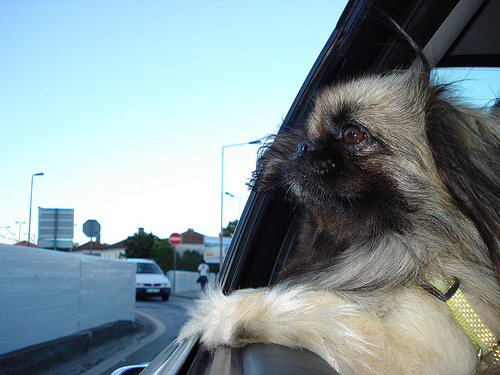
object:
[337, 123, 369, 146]
eye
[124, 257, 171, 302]
van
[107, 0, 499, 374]
car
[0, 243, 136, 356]
wall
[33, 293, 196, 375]
road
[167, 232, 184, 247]
sign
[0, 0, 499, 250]
sky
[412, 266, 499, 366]
strap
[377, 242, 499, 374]
back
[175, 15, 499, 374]
dog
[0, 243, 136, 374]
building